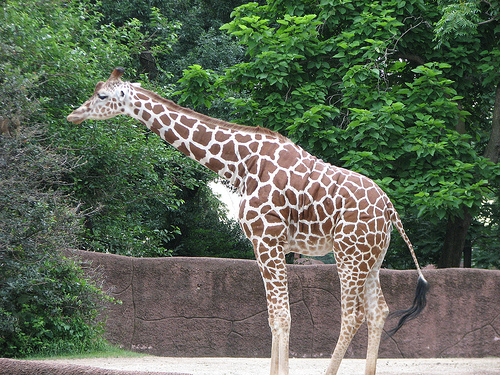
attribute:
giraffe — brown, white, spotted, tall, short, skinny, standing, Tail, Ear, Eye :
[66, 68, 439, 374]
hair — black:
[380, 275, 437, 345]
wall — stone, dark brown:
[58, 239, 498, 367]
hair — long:
[380, 270, 440, 350]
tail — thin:
[389, 216, 431, 286]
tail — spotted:
[383, 207, 437, 295]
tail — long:
[391, 209, 437, 291]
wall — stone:
[56, 250, 496, 354]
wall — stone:
[71, 243, 498, 355]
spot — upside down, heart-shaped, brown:
[251, 154, 285, 183]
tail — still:
[382, 213, 442, 352]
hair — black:
[381, 282, 435, 343]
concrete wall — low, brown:
[72, 245, 493, 358]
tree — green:
[5, 3, 190, 253]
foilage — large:
[7, 13, 97, 78]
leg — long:
[252, 245, 296, 370]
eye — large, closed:
[93, 86, 110, 105]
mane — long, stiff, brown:
[137, 86, 283, 139]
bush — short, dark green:
[0, 263, 128, 358]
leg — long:
[318, 243, 365, 369]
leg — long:
[358, 272, 398, 373]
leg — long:
[276, 249, 290, 373]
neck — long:
[119, 91, 257, 191]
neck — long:
[129, 93, 263, 192]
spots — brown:
[226, 145, 319, 218]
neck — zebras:
[159, 100, 229, 193]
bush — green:
[0, 87, 79, 370]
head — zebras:
[52, 49, 146, 149]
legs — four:
[251, 223, 418, 362]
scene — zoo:
[0, 8, 484, 353]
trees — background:
[167, 26, 445, 164]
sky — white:
[362, 56, 416, 85]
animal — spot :
[62, 76, 435, 369]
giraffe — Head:
[57, 80, 432, 364]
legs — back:
[319, 259, 397, 371]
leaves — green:
[272, 35, 386, 98]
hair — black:
[388, 275, 428, 342]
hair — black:
[388, 280, 433, 332]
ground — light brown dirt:
[111, 354, 481, 373]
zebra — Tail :
[405, 362, 448, 369]